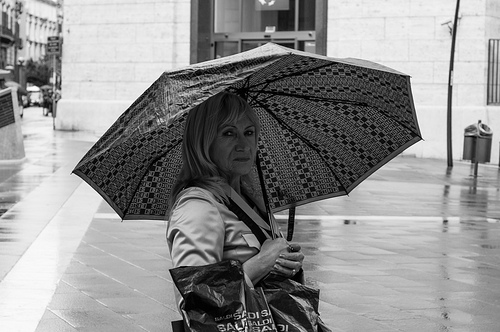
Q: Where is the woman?
A: Under the umbrella.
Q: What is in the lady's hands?
A: Shopping bags.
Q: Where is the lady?
A: In front of the store.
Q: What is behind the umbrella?
A: Glass door.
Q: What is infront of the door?
A: An umbrella.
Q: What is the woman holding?
A: An umbrella.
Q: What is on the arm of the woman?
A: A bag.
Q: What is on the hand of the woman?
A: A ring.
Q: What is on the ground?
A: Water.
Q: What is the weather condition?
A: Rainy.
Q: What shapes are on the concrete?
A: Diamonds.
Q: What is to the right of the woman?
A: A sign.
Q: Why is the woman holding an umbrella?
A: It is raining.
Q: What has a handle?
A: The umbrella.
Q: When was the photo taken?
A: During the daytime.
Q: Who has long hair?
A: The woman.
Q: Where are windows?
A: On buildings.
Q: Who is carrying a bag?
A: A woman.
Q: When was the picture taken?
A: Daytime.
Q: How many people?
A: One.